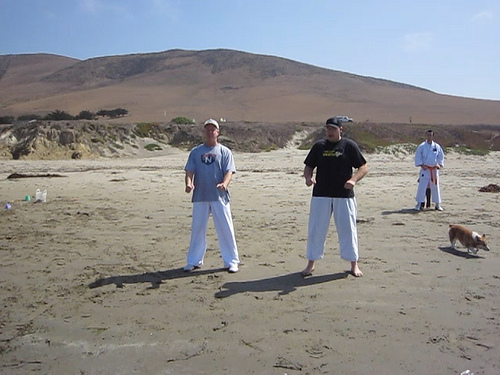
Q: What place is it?
A: It is a beach.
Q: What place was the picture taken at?
A: It was taken at the beach.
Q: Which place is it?
A: It is a beach.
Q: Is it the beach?
A: Yes, it is the beach.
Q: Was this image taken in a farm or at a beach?
A: It was taken at a beach.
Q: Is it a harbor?
A: No, it is a beach.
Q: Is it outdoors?
A: Yes, it is outdoors.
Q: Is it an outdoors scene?
A: Yes, it is outdoors.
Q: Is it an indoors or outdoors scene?
A: It is outdoors.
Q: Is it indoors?
A: No, it is outdoors.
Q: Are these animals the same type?
A: Yes, all the animals are dogs.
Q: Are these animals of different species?
A: No, all the animals are dogs.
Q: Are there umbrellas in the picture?
A: No, there are no umbrellas.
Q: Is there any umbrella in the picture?
A: No, there are no umbrellas.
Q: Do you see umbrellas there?
A: No, there are no umbrellas.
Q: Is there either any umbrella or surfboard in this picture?
A: No, there are no umbrellas or surfboards.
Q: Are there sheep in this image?
A: No, there are no sheep.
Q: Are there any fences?
A: No, there are no fences.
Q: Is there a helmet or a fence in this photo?
A: No, there are no fences or helmets.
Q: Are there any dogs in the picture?
A: Yes, there is a dog.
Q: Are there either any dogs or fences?
A: Yes, there is a dog.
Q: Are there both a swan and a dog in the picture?
A: No, there is a dog but no swans.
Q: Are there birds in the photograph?
A: No, there are no birds.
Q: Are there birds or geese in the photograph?
A: No, there are no birds or geese.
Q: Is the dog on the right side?
A: Yes, the dog is on the right of the image.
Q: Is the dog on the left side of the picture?
A: No, the dog is on the right of the image.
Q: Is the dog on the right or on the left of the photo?
A: The dog is on the right of the image.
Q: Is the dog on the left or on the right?
A: The dog is on the right of the image.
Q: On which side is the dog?
A: The dog is on the right of the image.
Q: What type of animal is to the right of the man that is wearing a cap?
A: The animal is a dog.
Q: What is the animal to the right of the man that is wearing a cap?
A: The animal is a dog.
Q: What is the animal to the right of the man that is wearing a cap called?
A: The animal is a dog.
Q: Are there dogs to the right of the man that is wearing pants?
A: Yes, there is a dog to the right of the man.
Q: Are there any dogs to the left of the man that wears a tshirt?
A: No, the dog is to the right of the man.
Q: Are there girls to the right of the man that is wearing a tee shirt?
A: No, there is a dog to the right of the man.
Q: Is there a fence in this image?
A: No, there are no fences.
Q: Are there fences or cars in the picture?
A: No, there are no fences or cars.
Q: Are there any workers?
A: No, there are no workers.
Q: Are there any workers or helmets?
A: No, there are no workers or helmets.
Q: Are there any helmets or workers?
A: No, there are no workers or helmets.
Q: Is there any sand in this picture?
A: Yes, there is sand.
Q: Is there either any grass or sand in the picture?
A: Yes, there is sand.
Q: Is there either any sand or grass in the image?
A: Yes, there is sand.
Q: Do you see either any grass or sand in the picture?
A: Yes, there is sand.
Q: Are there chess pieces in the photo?
A: No, there are no chess pieces.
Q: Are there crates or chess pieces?
A: No, there are no chess pieces or crates.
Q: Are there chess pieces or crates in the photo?
A: No, there are no chess pieces or crates.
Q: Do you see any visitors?
A: No, there are no visitors.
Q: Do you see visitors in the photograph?
A: No, there are no visitors.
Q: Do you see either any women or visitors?
A: No, there are no visitors or women.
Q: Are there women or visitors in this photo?
A: No, there are no visitors or women.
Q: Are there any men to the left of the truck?
A: Yes, there is a man to the left of the truck.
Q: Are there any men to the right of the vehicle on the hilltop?
A: No, the man is to the left of the truck.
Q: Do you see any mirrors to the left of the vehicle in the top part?
A: No, there is a man to the left of the truck.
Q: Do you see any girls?
A: No, there are no girls.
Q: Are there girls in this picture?
A: No, there are no girls.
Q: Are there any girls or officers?
A: No, there are no girls or officers.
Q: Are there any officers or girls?
A: No, there are no girls or officers.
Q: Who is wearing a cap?
A: The man is wearing a cap.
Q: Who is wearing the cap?
A: The man is wearing a cap.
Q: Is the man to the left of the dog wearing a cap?
A: Yes, the man is wearing a cap.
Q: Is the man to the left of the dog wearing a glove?
A: No, the man is wearing a cap.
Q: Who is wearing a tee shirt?
A: The man is wearing a tee shirt.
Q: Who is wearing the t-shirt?
A: The man is wearing a tee shirt.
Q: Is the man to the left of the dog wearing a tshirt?
A: Yes, the man is wearing a tshirt.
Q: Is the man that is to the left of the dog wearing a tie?
A: No, the man is wearing a tshirt.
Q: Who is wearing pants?
A: The man is wearing pants.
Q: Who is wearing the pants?
A: The man is wearing pants.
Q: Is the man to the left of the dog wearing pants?
A: Yes, the man is wearing pants.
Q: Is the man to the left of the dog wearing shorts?
A: No, the man is wearing pants.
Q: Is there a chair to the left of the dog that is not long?
A: No, there is a man to the left of the dog.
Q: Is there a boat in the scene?
A: No, there are no boats.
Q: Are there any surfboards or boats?
A: No, there are no boats or surfboards.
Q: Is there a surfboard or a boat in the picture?
A: No, there are no boats or surfboards.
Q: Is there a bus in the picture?
A: No, there are no buses.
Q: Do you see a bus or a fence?
A: No, there are no buses or fences.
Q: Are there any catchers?
A: No, there are no catchers.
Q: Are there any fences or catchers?
A: No, there are no catchers or fences.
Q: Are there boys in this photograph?
A: No, there are no boys.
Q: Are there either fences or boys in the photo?
A: No, there are no boys or fences.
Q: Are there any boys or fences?
A: No, there are no boys or fences.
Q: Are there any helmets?
A: No, there are no helmets.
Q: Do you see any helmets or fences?
A: No, there are no helmets or fences.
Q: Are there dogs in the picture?
A: Yes, there is a dog.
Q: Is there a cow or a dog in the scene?
A: Yes, there is a dog.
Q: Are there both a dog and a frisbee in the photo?
A: No, there is a dog but no frisbees.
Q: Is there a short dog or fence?
A: Yes, there is a short dog.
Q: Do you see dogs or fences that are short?
A: Yes, the dog is short.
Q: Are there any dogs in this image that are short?
A: Yes, there is a short dog.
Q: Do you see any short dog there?
A: Yes, there is a short dog.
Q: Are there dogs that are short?
A: Yes, there is a dog that is short.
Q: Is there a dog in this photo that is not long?
A: Yes, there is a short dog.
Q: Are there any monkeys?
A: No, there are no monkeys.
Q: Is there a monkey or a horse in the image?
A: No, there are no monkeys or horses.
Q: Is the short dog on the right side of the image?
A: Yes, the dog is on the right of the image.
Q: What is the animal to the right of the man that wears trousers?
A: The animal is a dog.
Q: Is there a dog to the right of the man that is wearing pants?
A: Yes, there is a dog to the right of the man.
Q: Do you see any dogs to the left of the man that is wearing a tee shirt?
A: No, the dog is to the right of the man.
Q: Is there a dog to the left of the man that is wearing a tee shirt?
A: No, the dog is to the right of the man.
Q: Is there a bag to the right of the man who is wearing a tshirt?
A: No, there is a dog to the right of the man.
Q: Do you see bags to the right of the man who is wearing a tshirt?
A: No, there is a dog to the right of the man.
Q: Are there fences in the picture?
A: No, there are no fences.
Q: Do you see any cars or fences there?
A: No, there are no fences or cars.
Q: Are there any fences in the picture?
A: No, there are no fences.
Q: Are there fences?
A: No, there are no fences.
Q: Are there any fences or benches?
A: No, there are no fences or benches.